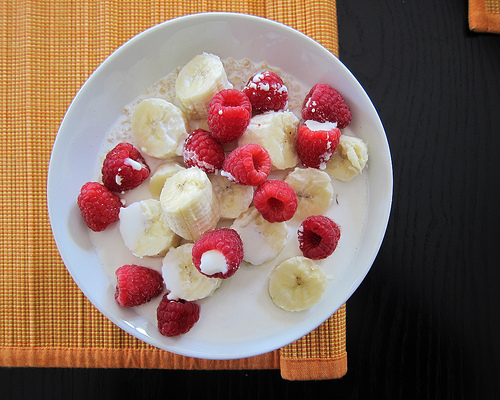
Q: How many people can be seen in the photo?
A: Zero.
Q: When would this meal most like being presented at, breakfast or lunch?
A: Breakfast.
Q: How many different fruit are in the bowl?
A: Two.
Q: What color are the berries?
A: Red.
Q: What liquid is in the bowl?
A: Milk.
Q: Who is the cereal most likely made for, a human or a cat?
A: A human.